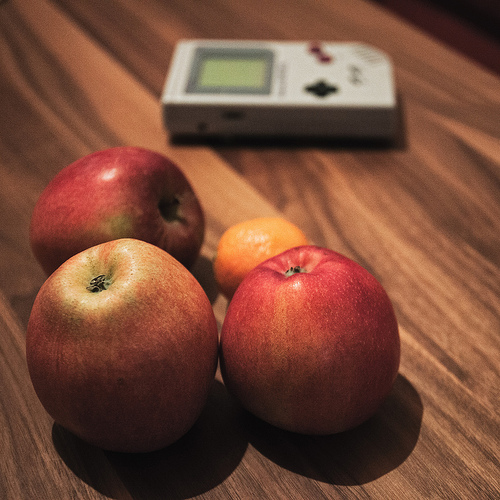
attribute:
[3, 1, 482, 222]
table — brown, wood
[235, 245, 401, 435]
apple — red, green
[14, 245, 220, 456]
apple — red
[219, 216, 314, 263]
orange — fruit, round, tasty, tangerine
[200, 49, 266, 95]
square — green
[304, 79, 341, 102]
cross — black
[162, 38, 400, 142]
device — white, gray, old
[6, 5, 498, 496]
room — kitchen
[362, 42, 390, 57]
corner — slanted